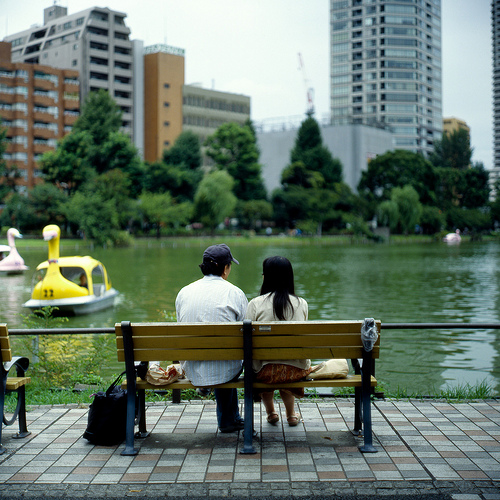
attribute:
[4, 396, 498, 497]
sidewalk — tiled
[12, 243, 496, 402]
water — greenish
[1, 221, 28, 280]
swan boat — pink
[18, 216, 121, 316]
boat — blue, yellow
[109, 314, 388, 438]
park bench — metal-framed, wooden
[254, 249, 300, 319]
hair — long, black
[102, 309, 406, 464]
bench — metal, wood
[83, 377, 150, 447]
bag — black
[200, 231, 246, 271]
cap — black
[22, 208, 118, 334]
boat — blue, yellow, duck shaped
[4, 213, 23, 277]
boat — pink, white, is duck shaped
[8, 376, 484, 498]
deck — small, brick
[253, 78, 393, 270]
tree — pine, large, green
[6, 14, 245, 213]
building — orange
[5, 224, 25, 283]
boat — white, duck shaped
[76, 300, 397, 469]
benches — wooden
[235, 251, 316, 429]
lady — sitting 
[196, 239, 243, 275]
hat — blue 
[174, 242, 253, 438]
man — sitting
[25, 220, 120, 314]
boat — yellow 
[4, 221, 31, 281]
boat — pink swan 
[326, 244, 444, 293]
water —  greenish 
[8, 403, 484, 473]
sidewalk — tiled 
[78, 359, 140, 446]
bag — black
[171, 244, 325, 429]
people — 2 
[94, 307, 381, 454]
bench — metal , wooden 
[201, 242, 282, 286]
cap — blue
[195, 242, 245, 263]
cap — black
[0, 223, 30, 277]
duck boat — pink and white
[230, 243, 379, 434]
lady — long haired, watching